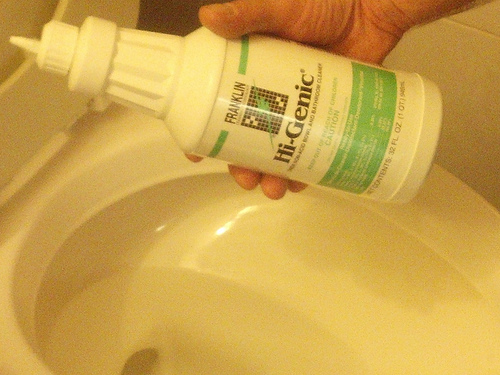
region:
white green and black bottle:
[13, 6, 472, 212]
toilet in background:
[1, 7, 498, 336]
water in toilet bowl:
[25, 258, 403, 370]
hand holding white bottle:
[179, 0, 498, 215]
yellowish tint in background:
[8, 10, 490, 337]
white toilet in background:
[8, 3, 493, 368]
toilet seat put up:
[4, 0, 220, 215]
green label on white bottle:
[312, 38, 429, 204]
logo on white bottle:
[210, 23, 348, 189]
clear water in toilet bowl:
[12, 108, 478, 372]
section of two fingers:
[254, 182, 282, 187]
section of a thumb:
[287, 6, 318, 12]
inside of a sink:
[116, 174, 140, 231]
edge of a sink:
[457, 227, 482, 246]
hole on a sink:
[128, 355, 140, 366]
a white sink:
[372, 254, 397, 271]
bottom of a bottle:
[421, 122, 437, 149]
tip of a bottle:
[41, 42, 52, 61]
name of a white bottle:
[282, 97, 306, 154]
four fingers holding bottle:
[176, 148, 308, 215]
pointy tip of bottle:
[0, 32, 54, 54]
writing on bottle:
[236, 41, 359, 163]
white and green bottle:
[16, 8, 460, 199]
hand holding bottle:
[205, 5, 465, 89]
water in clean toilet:
[49, 277, 369, 372]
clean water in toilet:
[38, 279, 382, 369]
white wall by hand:
[421, 21, 480, 136]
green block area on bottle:
[316, 58, 400, 195]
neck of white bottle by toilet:
[89, 25, 220, 102]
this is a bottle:
[243, 77, 367, 172]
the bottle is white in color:
[165, 52, 223, 110]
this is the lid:
[36, 13, 100, 89]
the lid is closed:
[12, 11, 113, 102]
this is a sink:
[173, 225, 351, 355]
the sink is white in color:
[137, 234, 329, 370]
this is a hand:
[331, 5, 386, 47]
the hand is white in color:
[325, 5, 379, 57]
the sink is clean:
[181, 222, 322, 339]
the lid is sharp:
[9, 23, 33, 58]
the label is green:
[261, 72, 422, 197]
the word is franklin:
[217, 69, 268, 138]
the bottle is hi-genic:
[280, 54, 334, 182]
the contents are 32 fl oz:
[378, 107, 421, 188]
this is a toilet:
[81, 193, 291, 341]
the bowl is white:
[85, 186, 212, 311]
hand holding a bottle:
[178, 4, 418, 290]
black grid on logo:
[212, 78, 408, 207]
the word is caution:
[318, 106, 369, 181]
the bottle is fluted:
[3, 15, 480, 249]